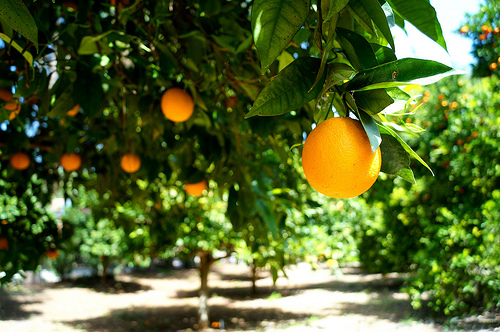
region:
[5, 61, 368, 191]
oranges in the tree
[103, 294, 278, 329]
shadow of the trees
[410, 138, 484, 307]
the bushes are large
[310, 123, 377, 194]
the orange is hanging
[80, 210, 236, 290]
the trees are blurry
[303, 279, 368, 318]
sand on the ground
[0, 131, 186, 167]
oranges in the tree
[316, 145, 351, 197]
skin on the orange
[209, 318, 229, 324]
orange on the ground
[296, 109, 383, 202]
an orange hanging on a tree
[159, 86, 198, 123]
an orange hanging on a tree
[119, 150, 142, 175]
an orange hanging on a tree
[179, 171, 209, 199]
an orange hanging on a tree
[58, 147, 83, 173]
an orange hanging on a tree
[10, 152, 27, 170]
an orange hanging on a tree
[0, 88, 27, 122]
an orange hanging on a tree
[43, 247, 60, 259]
an orange hanging on a tree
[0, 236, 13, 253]
an orange hanging on a tree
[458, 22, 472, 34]
an orange hanging on a tree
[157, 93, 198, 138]
orange in the tree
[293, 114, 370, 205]
orange in the tree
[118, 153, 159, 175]
orange in the tree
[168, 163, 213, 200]
orange in the tree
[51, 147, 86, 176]
orange in the tree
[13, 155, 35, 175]
orange in the tree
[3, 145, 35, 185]
orange in the tree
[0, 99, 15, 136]
orange in the tree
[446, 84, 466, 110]
orange in the tree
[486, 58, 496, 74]
orange in the tree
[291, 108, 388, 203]
a orange on a tree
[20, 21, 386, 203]
oranges on trees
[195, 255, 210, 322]
a gray truck of a tree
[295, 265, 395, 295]
gray shadows under the tree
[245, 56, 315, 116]
dark green tree leaf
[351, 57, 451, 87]
a bug hole in a leaf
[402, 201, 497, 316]
a green leafy tree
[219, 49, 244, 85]
a brown tree limb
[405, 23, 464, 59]
a clear blue sky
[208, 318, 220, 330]
oranges on the ground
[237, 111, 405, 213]
this is an orange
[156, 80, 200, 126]
this is an orange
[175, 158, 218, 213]
this is an orange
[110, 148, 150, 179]
this is an orange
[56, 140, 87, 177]
this is an orange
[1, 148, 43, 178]
this is an orange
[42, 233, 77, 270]
this is an orange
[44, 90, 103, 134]
this is an orange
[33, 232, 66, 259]
this is an orange